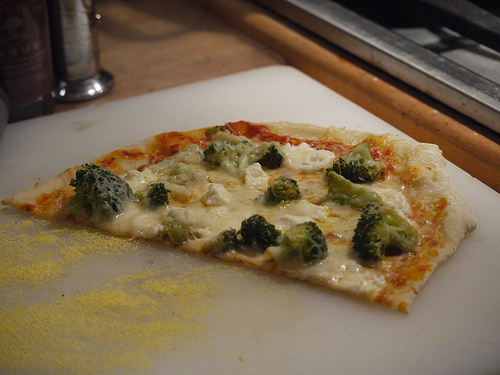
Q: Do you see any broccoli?
A: Yes, there is broccoli.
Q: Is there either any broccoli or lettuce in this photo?
A: Yes, there is broccoli.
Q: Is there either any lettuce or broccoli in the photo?
A: Yes, there is broccoli.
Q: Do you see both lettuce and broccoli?
A: No, there is broccoli but no lettuce.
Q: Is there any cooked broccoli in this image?
A: Yes, there is cooked broccoli.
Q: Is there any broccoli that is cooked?
A: Yes, there is broccoli that is cooked.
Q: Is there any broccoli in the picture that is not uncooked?
A: Yes, there is cooked broccoli.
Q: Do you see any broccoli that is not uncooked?
A: Yes, there is cooked broccoli.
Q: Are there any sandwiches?
A: No, there are no sandwiches.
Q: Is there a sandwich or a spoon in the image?
A: No, there are no sandwiches or spoons.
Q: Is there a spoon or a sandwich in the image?
A: No, there are no sandwiches or spoons.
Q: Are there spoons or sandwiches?
A: No, there are no sandwiches or spoons.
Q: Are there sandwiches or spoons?
A: No, there are no sandwiches or spoons.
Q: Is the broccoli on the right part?
A: Yes, the broccoli is on the right of the image.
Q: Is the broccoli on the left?
A: No, the broccoli is on the right of the image.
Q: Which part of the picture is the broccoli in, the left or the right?
A: The broccoli is on the right of the image.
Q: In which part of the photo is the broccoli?
A: The broccoli is on the right of the image.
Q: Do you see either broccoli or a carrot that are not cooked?
A: No, there is broccoli but it is cooked.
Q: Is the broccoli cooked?
A: Yes, the broccoli is cooked.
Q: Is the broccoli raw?
A: No, the broccoli is cooked.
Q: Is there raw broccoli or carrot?
A: No, there is broccoli but it is cooked.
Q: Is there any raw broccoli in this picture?
A: No, there is broccoli but it is cooked.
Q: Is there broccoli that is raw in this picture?
A: No, there is broccoli but it is cooked.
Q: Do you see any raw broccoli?
A: No, there is broccoli but it is cooked.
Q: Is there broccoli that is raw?
A: No, there is broccoli but it is cooked.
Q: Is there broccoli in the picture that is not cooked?
A: No, there is broccoli but it is cooked.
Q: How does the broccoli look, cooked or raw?
A: The broccoli is cooked.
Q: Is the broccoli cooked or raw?
A: The broccoli is cooked.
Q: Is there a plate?
A: Yes, there is a plate.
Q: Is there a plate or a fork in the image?
A: Yes, there is a plate.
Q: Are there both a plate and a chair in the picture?
A: No, there is a plate but no chairs.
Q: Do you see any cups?
A: No, there are no cups.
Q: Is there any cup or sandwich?
A: No, there are no cups or sandwiches.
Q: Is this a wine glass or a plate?
A: This is a plate.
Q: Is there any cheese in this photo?
A: Yes, there is cheese.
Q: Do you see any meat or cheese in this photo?
A: Yes, there is cheese.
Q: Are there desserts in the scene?
A: No, there are no desserts.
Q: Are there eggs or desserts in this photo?
A: No, there are no desserts or eggs.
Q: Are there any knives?
A: No, there are no knives.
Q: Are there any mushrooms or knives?
A: No, there are no knives or mushrooms.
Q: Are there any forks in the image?
A: No, there are no forks.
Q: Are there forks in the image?
A: No, there are no forks.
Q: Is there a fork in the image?
A: No, there are no forks.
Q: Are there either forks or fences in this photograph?
A: No, there are no forks or fences.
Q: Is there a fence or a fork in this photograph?
A: No, there are no forks or fences.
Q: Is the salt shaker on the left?
A: Yes, the salt shaker is on the left of the image.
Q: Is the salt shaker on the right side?
A: No, the salt shaker is on the left of the image.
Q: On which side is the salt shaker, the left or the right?
A: The salt shaker is on the left of the image.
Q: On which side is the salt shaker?
A: The salt shaker is on the left of the image.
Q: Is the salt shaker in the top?
A: Yes, the salt shaker is in the top of the image.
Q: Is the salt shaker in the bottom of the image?
A: No, the salt shaker is in the top of the image.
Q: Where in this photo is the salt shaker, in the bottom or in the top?
A: The salt shaker is in the top of the image.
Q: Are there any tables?
A: Yes, there is a table.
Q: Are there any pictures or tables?
A: Yes, there is a table.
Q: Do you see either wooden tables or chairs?
A: Yes, there is a wood table.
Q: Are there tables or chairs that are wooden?
A: Yes, the table is wooden.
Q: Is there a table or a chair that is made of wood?
A: Yes, the table is made of wood.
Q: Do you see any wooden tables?
A: Yes, there is a wood table.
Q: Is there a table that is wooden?
A: Yes, there is a table that is wooden.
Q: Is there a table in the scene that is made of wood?
A: Yes, there is a table that is made of wood.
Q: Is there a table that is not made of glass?
A: Yes, there is a table that is made of wood.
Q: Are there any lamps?
A: No, there are no lamps.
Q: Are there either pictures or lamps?
A: No, there are no lamps or pictures.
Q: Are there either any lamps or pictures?
A: No, there are no lamps or pictures.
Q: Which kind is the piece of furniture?
A: The piece of furniture is a table.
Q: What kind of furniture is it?
A: The piece of furniture is a table.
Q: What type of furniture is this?
A: That is a table.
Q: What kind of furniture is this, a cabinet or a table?
A: That is a table.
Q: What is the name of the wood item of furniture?
A: The piece of furniture is a table.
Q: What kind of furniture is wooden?
A: The furniture is a table.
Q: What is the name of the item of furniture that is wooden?
A: The piece of furniture is a table.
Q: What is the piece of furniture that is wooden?
A: The piece of furniture is a table.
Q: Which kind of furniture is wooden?
A: The furniture is a table.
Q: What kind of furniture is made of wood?
A: The furniture is a table.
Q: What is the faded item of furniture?
A: The piece of furniture is a table.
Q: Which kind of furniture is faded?
A: The furniture is a table.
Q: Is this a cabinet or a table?
A: This is a table.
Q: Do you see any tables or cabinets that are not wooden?
A: No, there is a table but it is wooden.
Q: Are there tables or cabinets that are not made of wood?
A: No, there is a table but it is made of wood.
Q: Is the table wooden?
A: Yes, the table is wooden.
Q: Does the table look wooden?
A: Yes, the table is wooden.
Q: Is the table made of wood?
A: Yes, the table is made of wood.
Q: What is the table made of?
A: The table is made of wood.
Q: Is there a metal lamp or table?
A: No, there is a table but it is wooden.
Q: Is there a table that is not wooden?
A: No, there is a table but it is wooden.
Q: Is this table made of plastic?
A: No, the table is made of wood.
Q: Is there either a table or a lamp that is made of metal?
A: No, there is a table but it is made of wood.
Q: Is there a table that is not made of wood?
A: No, there is a table but it is made of wood.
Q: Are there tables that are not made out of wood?
A: No, there is a table but it is made of wood.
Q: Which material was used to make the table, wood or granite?
A: The table is made of wood.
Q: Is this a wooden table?
A: Yes, this is a wooden table.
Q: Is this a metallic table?
A: No, this is a wooden table.